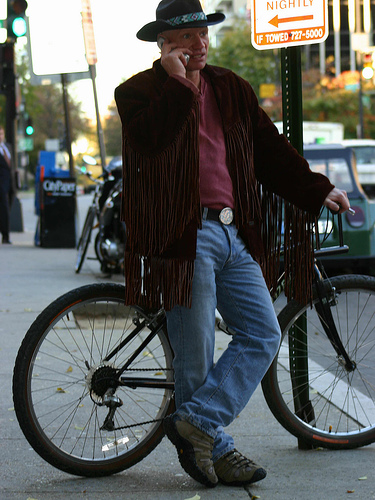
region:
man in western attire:
[113, 0, 350, 489]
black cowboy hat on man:
[135, 0, 225, 41]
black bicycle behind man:
[11, 197, 374, 476]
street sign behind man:
[249, 0, 328, 49]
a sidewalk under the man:
[1, 227, 373, 497]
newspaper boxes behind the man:
[34, 151, 76, 247]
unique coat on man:
[113, 58, 334, 310]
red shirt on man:
[169, 68, 235, 211]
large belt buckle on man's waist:
[218, 207, 233, 224]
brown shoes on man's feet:
[164, 413, 266, 484]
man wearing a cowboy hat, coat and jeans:
[103, 8, 356, 302]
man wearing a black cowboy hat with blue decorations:
[116, 5, 259, 88]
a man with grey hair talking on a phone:
[83, 1, 268, 149]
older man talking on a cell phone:
[95, 2, 280, 135]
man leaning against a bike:
[6, 2, 349, 486]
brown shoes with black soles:
[155, 394, 283, 489]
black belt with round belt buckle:
[172, 180, 277, 237]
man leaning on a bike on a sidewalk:
[7, 7, 368, 484]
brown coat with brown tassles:
[91, 54, 346, 319]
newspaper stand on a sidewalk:
[29, 159, 87, 259]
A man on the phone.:
[113, 0, 350, 489]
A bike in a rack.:
[10, 208, 373, 478]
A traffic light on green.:
[22, 112, 34, 139]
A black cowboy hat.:
[135, 0, 226, 43]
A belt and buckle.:
[200, 205, 236, 225]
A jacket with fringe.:
[113, 59, 335, 313]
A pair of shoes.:
[163, 415, 267, 490]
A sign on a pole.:
[249, 0, 328, 451]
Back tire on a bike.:
[10, 282, 175, 476]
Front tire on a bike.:
[261, 272, 374, 450]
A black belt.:
[196, 203, 236, 226]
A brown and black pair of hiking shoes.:
[163, 406, 266, 486]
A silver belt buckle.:
[216, 205, 235, 224]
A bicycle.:
[15, 193, 373, 475]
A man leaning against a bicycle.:
[16, 0, 373, 488]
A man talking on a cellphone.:
[111, 0, 353, 493]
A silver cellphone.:
[155, 38, 189, 62]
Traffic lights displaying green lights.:
[10, 1, 37, 138]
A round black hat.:
[133, 1, 226, 39]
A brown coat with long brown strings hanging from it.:
[112, 59, 333, 308]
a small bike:
[11, 202, 373, 498]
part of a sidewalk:
[0, 217, 373, 499]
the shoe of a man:
[167, 411, 218, 487]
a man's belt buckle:
[205, 199, 237, 225]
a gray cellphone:
[152, 36, 191, 69]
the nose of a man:
[191, 33, 208, 50]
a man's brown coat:
[110, 61, 335, 309]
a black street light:
[23, 110, 34, 138]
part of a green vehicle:
[262, 131, 373, 290]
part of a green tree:
[301, 88, 370, 138]